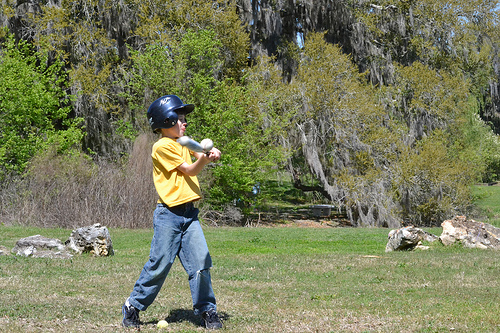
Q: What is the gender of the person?
A: Male.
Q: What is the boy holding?
A: Bat.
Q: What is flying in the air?
A: Ball.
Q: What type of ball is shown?
A: Base ball.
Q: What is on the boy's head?
A: Helmet.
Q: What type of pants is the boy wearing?
A: Denim.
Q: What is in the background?
A: Trees.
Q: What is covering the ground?
A: Grass.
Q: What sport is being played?
A: Baseball.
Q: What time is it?
A: Afternoon.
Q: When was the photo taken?
A: During the daytime.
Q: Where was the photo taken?
A: During the daytime.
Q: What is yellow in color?
A: Shirt.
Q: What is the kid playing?
A: Baseball.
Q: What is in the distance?
A: Trees.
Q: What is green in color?
A: Grass.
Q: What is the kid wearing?
A: Helmet.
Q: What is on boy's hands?
A: Bat.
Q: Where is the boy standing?
A: In the field.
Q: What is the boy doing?
A: Swinging a bat.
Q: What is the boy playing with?
A: A bat.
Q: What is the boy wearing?
A: A black helmet.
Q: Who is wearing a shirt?
A: A boy.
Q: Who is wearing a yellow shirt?
A: A boy.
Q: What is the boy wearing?
A: Pants.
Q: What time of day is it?
A: Daytime.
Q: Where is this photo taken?
A: On a grassy field.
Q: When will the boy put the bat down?
A: After he hits the ball.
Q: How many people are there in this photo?
A: One.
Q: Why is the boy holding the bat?
A: He is trying to hit the ball.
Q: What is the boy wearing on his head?
A: A helmet.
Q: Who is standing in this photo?
A: A boy.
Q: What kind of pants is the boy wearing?
A: Jean.